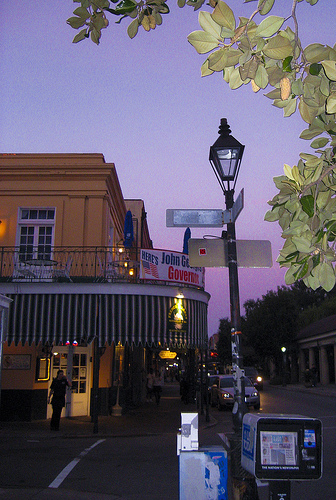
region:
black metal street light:
[207, 118, 261, 427]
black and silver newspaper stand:
[247, 415, 324, 487]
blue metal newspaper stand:
[167, 445, 248, 499]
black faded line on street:
[68, 444, 104, 485]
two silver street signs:
[165, 200, 271, 271]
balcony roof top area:
[34, 234, 210, 281]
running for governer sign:
[144, 238, 210, 284]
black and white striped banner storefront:
[27, 292, 215, 352]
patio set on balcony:
[11, 257, 83, 275]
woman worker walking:
[47, 365, 85, 438]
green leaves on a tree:
[187, 8, 331, 100]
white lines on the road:
[36, 432, 143, 496]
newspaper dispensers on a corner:
[172, 402, 326, 498]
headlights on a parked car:
[218, 387, 257, 407]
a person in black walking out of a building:
[45, 370, 73, 430]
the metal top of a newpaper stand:
[173, 407, 201, 449]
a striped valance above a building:
[10, 296, 167, 352]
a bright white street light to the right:
[277, 344, 288, 351]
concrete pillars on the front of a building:
[297, 350, 334, 384]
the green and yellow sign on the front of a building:
[167, 302, 189, 333]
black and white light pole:
[162, 105, 275, 374]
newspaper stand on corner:
[209, 401, 332, 496]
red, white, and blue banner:
[131, 244, 210, 288]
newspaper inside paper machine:
[252, 420, 307, 476]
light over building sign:
[152, 277, 207, 344]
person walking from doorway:
[45, 339, 108, 424]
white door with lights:
[33, 329, 110, 430]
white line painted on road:
[50, 432, 100, 495]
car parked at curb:
[175, 353, 269, 431]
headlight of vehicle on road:
[235, 358, 275, 405]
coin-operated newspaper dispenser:
[232, 399, 327, 498]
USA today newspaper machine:
[236, 395, 330, 498]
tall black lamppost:
[161, 110, 288, 415]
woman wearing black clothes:
[45, 360, 88, 438]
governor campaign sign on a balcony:
[134, 235, 215, 300]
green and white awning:
[36, 290, 220, 349]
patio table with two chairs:
[2, 240, 84, 287]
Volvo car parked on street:
[208, 372, 271, 413]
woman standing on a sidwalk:
[33, 364, 87, 441]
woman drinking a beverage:
[29, 350, 104, 480]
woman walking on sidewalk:
[45, 367, 71, 429]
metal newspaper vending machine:
[241, 412, 320, 498]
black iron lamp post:
[208, 116, 251, 498]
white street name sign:
[163, 186, 244, 227]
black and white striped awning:
[2, 295, 209, 350]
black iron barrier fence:
[2, 243, 141, 282]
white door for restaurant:
[44, 346, 89, 418]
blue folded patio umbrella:
[121, 208, 136, 262]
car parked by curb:
[210, 373, 259, 409]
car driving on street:
[242, 362, 270, 390]